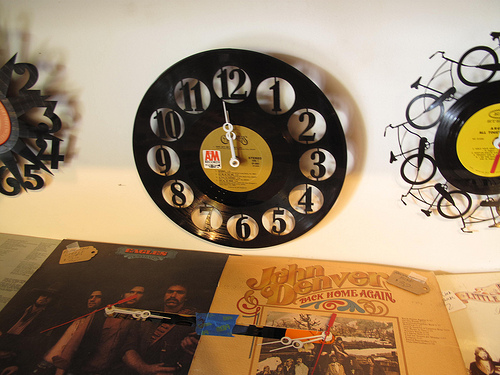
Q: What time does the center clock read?
A: 12.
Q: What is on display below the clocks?
A: Record albums.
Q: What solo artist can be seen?
A: John Denver.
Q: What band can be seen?
A: The eagles.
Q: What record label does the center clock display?
A: A & M records.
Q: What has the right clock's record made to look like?
A: Many bikes.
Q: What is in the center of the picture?
A: A clock with numbers.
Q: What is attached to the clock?
A: Arms.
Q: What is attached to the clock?
A: White arms.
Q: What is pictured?
A: A black clock with arms.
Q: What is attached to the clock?
A: White arms.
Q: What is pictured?
A: A vinyl clock with arms.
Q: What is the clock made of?
A: A vinyl record.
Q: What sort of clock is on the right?
A: A clock with bicycle shapes attached.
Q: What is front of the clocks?
A: A John Denver album cover.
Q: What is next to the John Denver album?
A: An Eagles Album.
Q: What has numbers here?
A: The clock.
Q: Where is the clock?
A: On the wall.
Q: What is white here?
A: The wall.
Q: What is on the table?
A: A magazine.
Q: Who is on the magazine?
A: A singer.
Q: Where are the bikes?
A: On the clock.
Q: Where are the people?
A: On the pictures.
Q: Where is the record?
A: On the wall.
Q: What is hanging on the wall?
A: A clock.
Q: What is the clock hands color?
A: White.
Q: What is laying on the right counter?
A: A clock with John Denver.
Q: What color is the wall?
A: White.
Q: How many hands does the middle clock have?
A: Two.